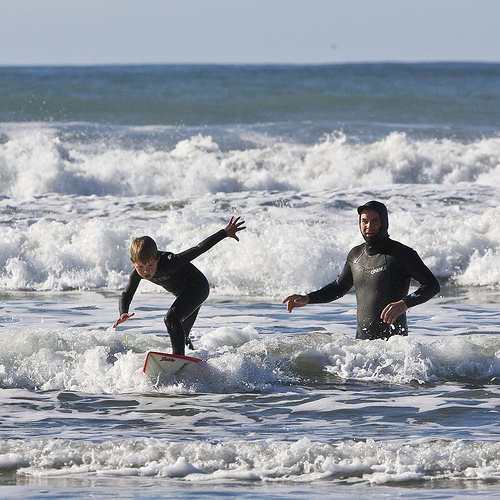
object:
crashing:
[0, 319, 499, 394]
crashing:
[0, 119, 498, 300]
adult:
[280, 199, 442, 345]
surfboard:
[140, 348, 202, 383]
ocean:
[0, 61, 499, 498]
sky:
[0, 0, 499, 64]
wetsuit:
[116, 228, 226, 356]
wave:
[0, 121, 499, 297]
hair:
[128, 234, 161, 265]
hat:
[354, 199, 390, 244]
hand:
[223, 213, 246, 241]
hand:
[110, 311, 136, 330]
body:
[0, 60, 499, 500]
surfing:
[112, 215, 247, 390]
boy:
[110, 213, 247, 356]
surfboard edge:
[147, 348, 205, 366]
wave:
[0, 321, 498, 394]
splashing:
[0, 435, 498, 489]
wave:
[0, 434, 499, 487]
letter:
[367, 265, 388, 278]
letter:
[152, 273, 172, 284]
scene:
[0, 0, 499, 499]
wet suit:
[303, 198, 440, 340]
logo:
[368, 265, 385, 277]